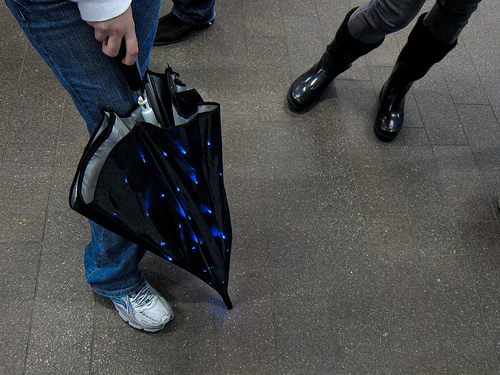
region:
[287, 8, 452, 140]
black rain boots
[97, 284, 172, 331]
white tennis shoe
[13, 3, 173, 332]
person with blue jeans and white shoes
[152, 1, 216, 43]
person with blue jeans and dark shoes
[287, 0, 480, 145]
person with gray pants and black boots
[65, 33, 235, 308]
black and blue umbrella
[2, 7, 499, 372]
brown tile floor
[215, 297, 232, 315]
reflection of blue light on the floor at tip of umbrella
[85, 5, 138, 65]
hand holding the umbrella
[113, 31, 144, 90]
black umbrella handle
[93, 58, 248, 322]
a black umbrella with blue marks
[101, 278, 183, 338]
a white tennis shoe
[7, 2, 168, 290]
a pair of blue jeans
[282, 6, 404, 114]
black boots on a woman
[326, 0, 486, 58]
gray pants ona woman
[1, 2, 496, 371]
a gray brick paved floor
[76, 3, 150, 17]
a white shirt on a woman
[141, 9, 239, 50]
a black shoe on a person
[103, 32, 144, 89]
the black handle of an umbrella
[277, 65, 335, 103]
light reflecting off the top of a black boot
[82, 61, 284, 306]
black and blue umbrella being held by woman in jeans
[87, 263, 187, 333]
white shoes worn by woman in jeans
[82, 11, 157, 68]
hand of woman in jeans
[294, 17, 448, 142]
black boots of woman standing next to the woman in jeans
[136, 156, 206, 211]
blue dots on the umbrella being held by the woman in jeans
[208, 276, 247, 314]
tip of black and blue umbrella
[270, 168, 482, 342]
street that woman in jeans is standing on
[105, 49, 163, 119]
handle of black and blue umbrella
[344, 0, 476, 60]
gray leggings worn by woman in black boots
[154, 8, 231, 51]
shoe of person standing behind the woman in jeans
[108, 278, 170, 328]
the dirty blue and grey sneaker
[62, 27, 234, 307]
a blue and black umbrella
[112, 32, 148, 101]
the handle of a blue and black umbrella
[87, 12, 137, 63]
a hand holding a handle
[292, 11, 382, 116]
a black rubber rain boot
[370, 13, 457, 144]
a black rubber rain boot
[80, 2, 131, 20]
the white cuff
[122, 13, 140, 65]
the pointer finger of a hand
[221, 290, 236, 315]
the plastic top of the umbrella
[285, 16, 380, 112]
a black boot on a woman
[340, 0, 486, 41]
grey pants on a woman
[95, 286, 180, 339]
a white tennis shoe on a woman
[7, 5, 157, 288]
blue jeans on a woman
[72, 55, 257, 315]
a black umbrella with glowing blue spots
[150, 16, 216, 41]
a black shoe on a person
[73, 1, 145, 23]
a white sleeve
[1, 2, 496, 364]
a grey brick paved walkway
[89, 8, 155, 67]
a hand of a woman